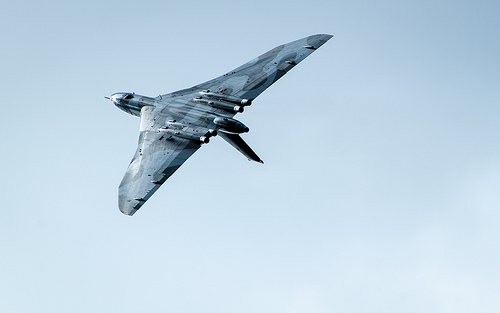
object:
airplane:
[104, 34, 334, 216]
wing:
[117, 116, 213, 217]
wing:
[191, 34, 332, 110]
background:
[0, 0, 499, 313]